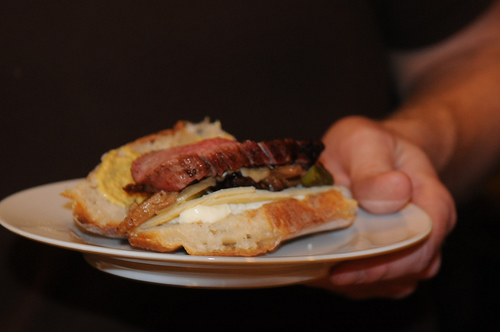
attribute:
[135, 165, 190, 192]
meat — sliced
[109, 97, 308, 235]
sandwhich — open, toasted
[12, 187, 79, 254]
plate — white, held, small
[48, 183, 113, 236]
bread — white, brown, crusty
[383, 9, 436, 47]
shirt — black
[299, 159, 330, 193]
pickles — green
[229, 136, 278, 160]
hot dog — greasy, cut